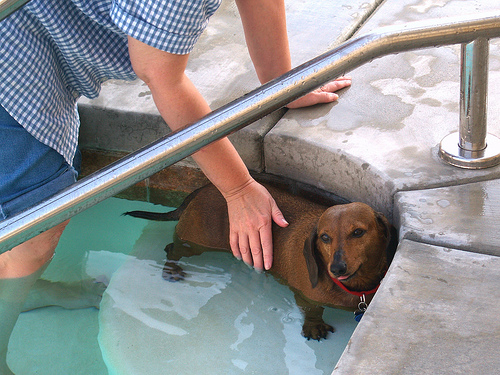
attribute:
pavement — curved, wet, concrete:
[235, 114, 435, 273]